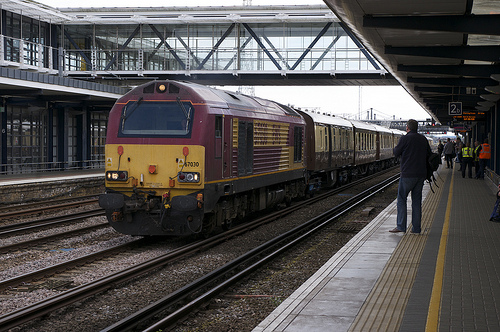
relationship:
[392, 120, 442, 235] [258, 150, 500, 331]
man on platform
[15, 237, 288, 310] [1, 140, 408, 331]
gravel between tracks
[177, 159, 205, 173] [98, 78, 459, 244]
numbers are on train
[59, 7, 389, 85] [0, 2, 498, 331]
walkway connects station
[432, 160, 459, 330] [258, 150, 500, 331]
line on platform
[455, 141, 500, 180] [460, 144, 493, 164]
men are wearing uniforms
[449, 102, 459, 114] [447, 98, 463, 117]
2 on sign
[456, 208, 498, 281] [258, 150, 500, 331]
pattern on platform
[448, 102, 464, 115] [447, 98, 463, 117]
2b on sign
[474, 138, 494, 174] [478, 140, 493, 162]
man wearing a jacket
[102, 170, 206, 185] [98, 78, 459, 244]
headlights are on train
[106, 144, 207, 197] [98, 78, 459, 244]
panel on train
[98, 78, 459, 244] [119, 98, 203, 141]
train has a windshield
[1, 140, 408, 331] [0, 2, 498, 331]
tracks are at station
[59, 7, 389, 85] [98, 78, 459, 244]
walkway over train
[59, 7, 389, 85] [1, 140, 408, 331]
walkway over tracks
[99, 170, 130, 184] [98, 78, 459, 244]
headlight on train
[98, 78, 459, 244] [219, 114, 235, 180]
train has a door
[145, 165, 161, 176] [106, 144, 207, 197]
object on panel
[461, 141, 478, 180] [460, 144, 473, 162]
men wearing a jacket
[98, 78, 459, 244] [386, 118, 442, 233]
train can carry man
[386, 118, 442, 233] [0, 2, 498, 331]
man are at station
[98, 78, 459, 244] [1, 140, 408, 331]
train on tracks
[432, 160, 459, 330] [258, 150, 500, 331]
line for safety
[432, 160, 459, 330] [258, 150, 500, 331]
line on safety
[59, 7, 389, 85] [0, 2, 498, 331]
walkway connecting station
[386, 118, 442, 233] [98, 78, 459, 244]
man are waiting for train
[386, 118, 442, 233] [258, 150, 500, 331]
man are on platform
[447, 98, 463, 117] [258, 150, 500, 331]
sign on platform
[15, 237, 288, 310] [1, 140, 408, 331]
gravel next to tracks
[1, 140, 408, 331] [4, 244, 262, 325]
tracks on ground